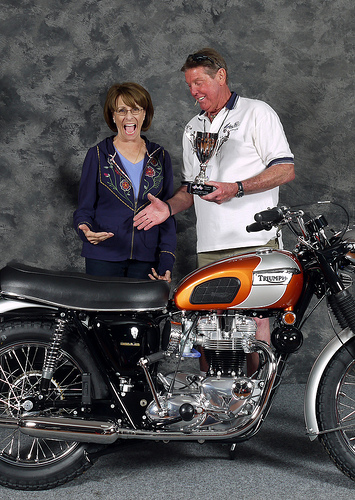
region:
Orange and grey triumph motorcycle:
[0, 192, 353, 490]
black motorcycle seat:
[0, 258, 170, 311]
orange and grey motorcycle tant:
[169, 239, 305, 312]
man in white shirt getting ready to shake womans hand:
[129, 45, 297, 381]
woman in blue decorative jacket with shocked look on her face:
[67, 80, 179, 285]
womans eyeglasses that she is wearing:
[112, 99, 144, 119]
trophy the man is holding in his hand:
[185, 127, 218, 200]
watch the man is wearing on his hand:
[231, 178, 245, 198]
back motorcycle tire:
[1, 313, 98, 492]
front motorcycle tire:
[314, 329, 354, 485]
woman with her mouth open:
[69, 74, 178, 282]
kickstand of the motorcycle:
[226, 443, 240, 459]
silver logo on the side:
[250, 265, 295, 291]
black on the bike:
[187, 274, 243, 312]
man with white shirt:
[175, 43, 302, 251]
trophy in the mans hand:
[182, 119, 231, 207]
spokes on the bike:
[3, 357, 28, 394]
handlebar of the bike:
[247, 211, 291, 226]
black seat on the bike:
[3, 267, 171, 314]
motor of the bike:
[165, 345, 257, 408]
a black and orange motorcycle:
[0, 200, 354, 487]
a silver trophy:
[184, 124, 229, 192]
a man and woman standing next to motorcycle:
[2, 47, 353, 489]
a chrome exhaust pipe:
[1, 415, 122, 443]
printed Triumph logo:
[257, 271, 287, 284]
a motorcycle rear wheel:
[0, 316, 107, 489]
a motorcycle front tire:
[315, 334, 353, 481]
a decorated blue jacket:
[75, 132, 176, 265]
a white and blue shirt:
[181, 90, 296, 253]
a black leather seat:
[1, 261, 169, 313]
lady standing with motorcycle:
[56, 71, 191, 280]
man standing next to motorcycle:
[127, 36, 312, 275]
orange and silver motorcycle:
[3, 182, 353, 497]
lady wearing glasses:
[100, 93, 171, 134]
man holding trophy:
[180, 124, 253, 226]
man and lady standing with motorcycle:
[72, 48, 299, 255]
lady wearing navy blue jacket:
[82, 87, 178, 281]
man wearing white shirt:
[173, 40, 309, 259]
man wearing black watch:
[222, 167, 265, 222]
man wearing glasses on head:
[162, 45, 260, 95]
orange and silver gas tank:
[172, 244, 300, 307]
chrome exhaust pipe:
[15, 316, 284, 438]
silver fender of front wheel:
[300, 317, 348, 437]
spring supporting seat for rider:
[37, 305, 62, 381]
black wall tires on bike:
[0, 309, 100, 484]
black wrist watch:
[229, 178, 246, 200]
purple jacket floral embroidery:
[230, 176, 245, 195]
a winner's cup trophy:
[179, 122, 230, 197]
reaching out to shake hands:
[130, 187, 177, 242]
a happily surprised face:
[104, 81, 151, 143]